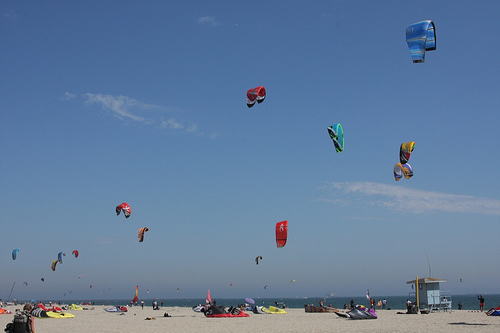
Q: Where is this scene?
A: Beach.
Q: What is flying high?
A: Kites.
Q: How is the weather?
A: Fair.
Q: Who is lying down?
A: Beachgoers.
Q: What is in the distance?
A: Ocean.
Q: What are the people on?
A: Sand.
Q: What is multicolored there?
A: The kites.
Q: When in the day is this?
A: Afternoon.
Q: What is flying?
A: Kites.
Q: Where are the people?
A: Beach.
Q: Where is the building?
A: Right side of the beach.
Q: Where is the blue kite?
A: Top right.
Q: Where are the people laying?
A: Beach.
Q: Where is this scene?
A: Beach.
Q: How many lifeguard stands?
A: One.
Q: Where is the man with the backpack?
A: Bottom left corner.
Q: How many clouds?
A: Two.